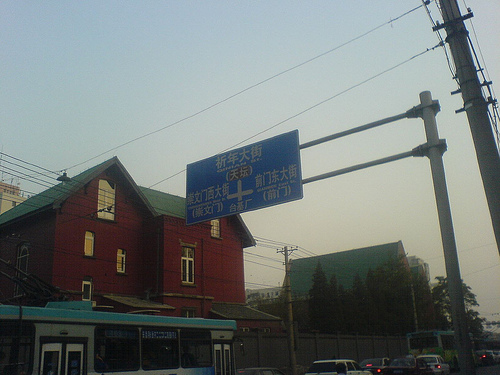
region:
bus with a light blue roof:
[3, 297, 238, 374]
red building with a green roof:
[1, 155, 283, 325]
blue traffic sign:
[182, 129, 304, 224]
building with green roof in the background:
[281, 236, 415, 298]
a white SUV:
[306, 355, 371, 373]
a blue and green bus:
[405, 328, 481, 368]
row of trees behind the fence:
[308, 256, 490, 336]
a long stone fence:
[227, 330, 409, 367]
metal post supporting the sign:
[296, 89, 476, 374]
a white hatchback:
[413, 351, 450, 373]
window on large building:
[88, 164, 123, 223]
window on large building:
[206, 208, 227, 241]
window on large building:
[174, 237, 201, 289]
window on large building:
[114, 243, 138, 283]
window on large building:
[75, 269, 107, 304]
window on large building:
[36, 333, 61, 373]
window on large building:
[62, 335, 87, 371]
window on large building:
[222, 338, 234, 370]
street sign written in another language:
[176, 139, 363, 229]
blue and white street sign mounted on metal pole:
[138, 134, 322, 232]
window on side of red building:
[73, 224, 112, 266]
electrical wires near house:
[13, 150, 53, 192]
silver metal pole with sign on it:
[401, 75, 468, 242]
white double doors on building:
[35, 326, 107, 365]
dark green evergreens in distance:
[308, 273, 398, 313]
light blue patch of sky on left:
[45, 33, 162, 93]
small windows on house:
[83, 165, 123, 219]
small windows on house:
[76, 224, 105, 258]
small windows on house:
[110, 241, 133, 275]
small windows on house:
[170, 234, 205, 290]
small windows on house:
[64, 272, 96, 300]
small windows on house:
[38, 333, 60, 370]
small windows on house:
[208, 343, 220, 373]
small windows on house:
[222, 339, 230, 369]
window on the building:
[181, 252, 196, 283]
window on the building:
[114, 249, 134, 276]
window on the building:
[82, 231, 100, 258]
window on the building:
[95, 180, 114, 220]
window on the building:
[66, 346, 82, 369]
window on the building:
[208, 343, 227, 370]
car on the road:
[426, 354, 453, 371]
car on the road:
[390, 356, 415, 371]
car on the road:
[316, 347, 370, 371]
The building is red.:
[29, 165, 266, 330]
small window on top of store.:
[208, 214, 232, 248]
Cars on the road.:
[353, 345, 460, 370]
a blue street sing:
[153, 108, 338, 248]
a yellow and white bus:
[393, 318, 473, 372]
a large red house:
[15, 160, 237, 305]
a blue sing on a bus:
[70, 321, 201, 358]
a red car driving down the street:
[385, 351, 436, 372]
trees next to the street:
[313, 258, 433, 332]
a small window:
[68, 215, 104, 272]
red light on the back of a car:
[361, 362, 388, 374]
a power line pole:
[198, 200, 343, 346]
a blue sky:
[11, 19, 473, 190]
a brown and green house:
[1, 143, 278, 350]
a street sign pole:
[161, 82, 487, 374]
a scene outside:
[9, 28, 499, 361]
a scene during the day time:
[9, 30, 499, 360]